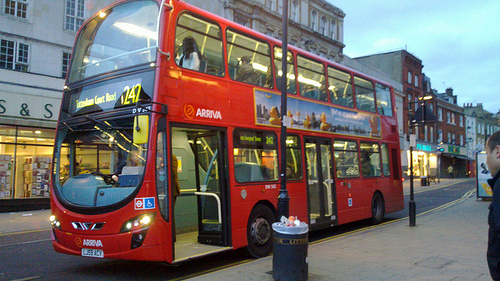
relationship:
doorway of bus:
[164, 126, 226, 249] [67, 8, 415, 259]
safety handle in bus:
[196, 189, 227, 223] [67, 8, 415, 259]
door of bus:
[173, 131, 227, 235] [67, 8, 415, 259]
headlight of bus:
[125, 213, 153, 238] [67, 8, 415, 259]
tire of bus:
[250, 209, 285, 255] [67, 8, 415, 259]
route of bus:
[71, 93, 121, 108] [67, 8, 415, 259]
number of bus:
[122, 84, 147, 107] [67, 8, 415, 259]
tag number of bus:
[81, 249, 111, 267] [67, 8, 415, 259]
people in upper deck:
[182, 35, 200, 69] [170, 25, 392, 113]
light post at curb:
[403, 129, 425, 226] [413, 198, 450, 221]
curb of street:
[413, 198, 450, 221] [7, 179, 475, 275]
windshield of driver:
[64, 132, 136, 187] [130, 124, 147, 179]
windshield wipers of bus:
[52, 118, 143, 140] [67, 8, 415, 259]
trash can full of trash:
[274, 203, 313, 280] [281, 214, 303, 226]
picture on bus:
[251, 91, 393, 139] [67, 8, 415, 259]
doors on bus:
[297, 140, 340, 220] [67, 8, 415, 259]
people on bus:
[182, 35, 200, 69] [67, 8, 415, 259]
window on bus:
[237, 125, 277, 178] [67, 8, 415, 259]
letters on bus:
[196, 106, 231, 124] [67, 8, 415, 259]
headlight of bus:
[49, 213, 64, 231] [67, 8, 415, 259]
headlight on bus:
[125, 213, 153, 238] [67, 8, 415, 259]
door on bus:
[173, 131, 227, 235] [67, 8, 415, 259]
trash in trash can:
[281, 214, 303, 226] [274, 203, 313, 280]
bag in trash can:
[281, 222, 305, 237] [274, 203, 313, 280]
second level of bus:
[170, 25, 392, 113] [67, 8, 415, 259]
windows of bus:
[167, 23, 373, 109] [67, 8, 415, 259]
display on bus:
[62, 79, 155, 104] [67, 8, 415, 259]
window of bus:
[75, 23, 166, 62] [67, 8, 415, 259]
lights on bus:
[68, 80, 148, 108] [67, 8, 415, 259]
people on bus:
[182, 35, 288, 84] [67, 8, 415, 259]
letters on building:
[1, 98, 56, 113] [5, 2, 334, 210]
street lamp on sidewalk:
[406, 130, 419, 227] [302, 182, 498, 275]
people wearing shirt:
[182, 35, 200, 69] [182, 54, 212, 77]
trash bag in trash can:
[277, 215, 307, 238] [274, 203, 313, 280]